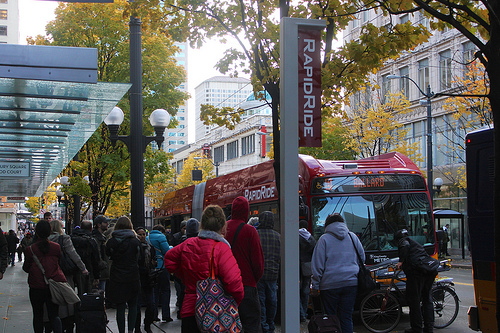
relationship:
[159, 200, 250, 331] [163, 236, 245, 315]
woman in jacket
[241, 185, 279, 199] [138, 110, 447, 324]
rapid ride on bus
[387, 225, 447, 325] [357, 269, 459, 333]
person with bicycle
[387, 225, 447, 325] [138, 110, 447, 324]
person front of bus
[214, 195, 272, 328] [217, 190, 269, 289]
person wearing hoodie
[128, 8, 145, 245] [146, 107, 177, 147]
light pole with street light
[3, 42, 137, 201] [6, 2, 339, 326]
roof over bus stop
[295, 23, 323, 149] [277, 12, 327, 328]
flag on pole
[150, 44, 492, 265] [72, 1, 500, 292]
buildings in background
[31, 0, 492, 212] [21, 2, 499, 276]
leaves on trees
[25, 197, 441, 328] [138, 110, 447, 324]
people getting on bus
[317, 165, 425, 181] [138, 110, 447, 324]
lights on bus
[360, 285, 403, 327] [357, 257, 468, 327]
wheel on bicycle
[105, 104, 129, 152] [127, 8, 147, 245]
street light on light pole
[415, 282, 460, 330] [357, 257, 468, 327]
wheel on bicycle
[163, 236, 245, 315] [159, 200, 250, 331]
jacket on woman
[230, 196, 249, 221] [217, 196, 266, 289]
hood on hoodie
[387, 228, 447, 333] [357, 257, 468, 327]
person with bicycle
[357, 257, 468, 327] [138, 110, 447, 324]
bicycle front of bus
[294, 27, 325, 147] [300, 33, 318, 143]
sign board with color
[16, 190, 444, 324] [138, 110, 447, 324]
group waiting for bus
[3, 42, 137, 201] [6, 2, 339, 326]
shelter in bus stand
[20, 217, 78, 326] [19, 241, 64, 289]
girl with shirt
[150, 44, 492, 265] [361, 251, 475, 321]
buildings on roadside